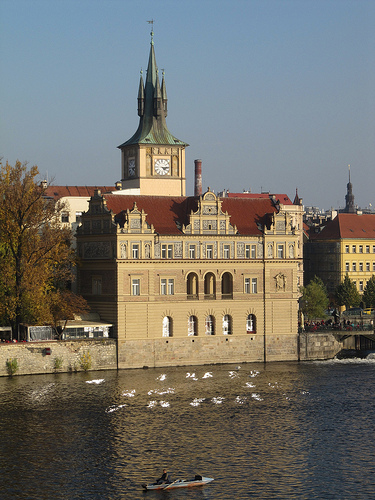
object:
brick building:
[76, 186, 303, 371]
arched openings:
[184, 269, 201, 301]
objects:
[83, 371, 112, 387]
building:
[79, 184, 309, 337]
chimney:
[191, 154, 204, 198]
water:
[0, 357, 361, 499]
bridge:
[300, 290, 368, 363]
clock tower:
[117, 16, 190, 197]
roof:
[117, 27, 192, 147]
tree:
[0, 154, 72, 344]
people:
[300, 307, 373, 340]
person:
[156, 465, 171, 478]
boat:
[131, 454, 233, 495]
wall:
[120, 256, 300, 336]